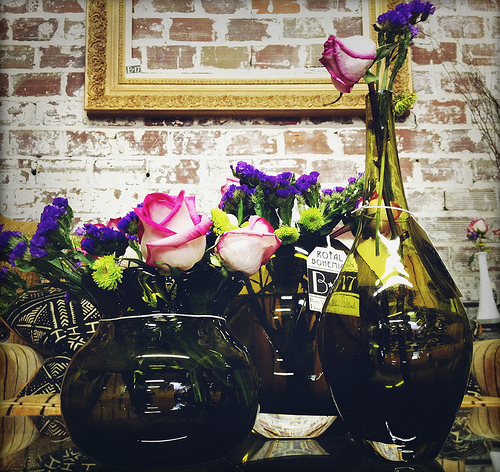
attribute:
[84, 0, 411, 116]
frame — gold, golden, empty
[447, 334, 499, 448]
couch — yellow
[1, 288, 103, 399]
pillow — black, tan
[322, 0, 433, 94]
flowers — red, blue, dried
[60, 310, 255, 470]
vase — glass, short, green, dark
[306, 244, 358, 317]
tag — black, white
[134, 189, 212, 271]
rose — white, pink, red, pale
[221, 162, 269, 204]
flower — purple, green, blue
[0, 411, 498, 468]
table — small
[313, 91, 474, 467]
vase — green, tall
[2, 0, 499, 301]
wall — brick, distressed brick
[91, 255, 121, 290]
flower — small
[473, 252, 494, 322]
vase — white